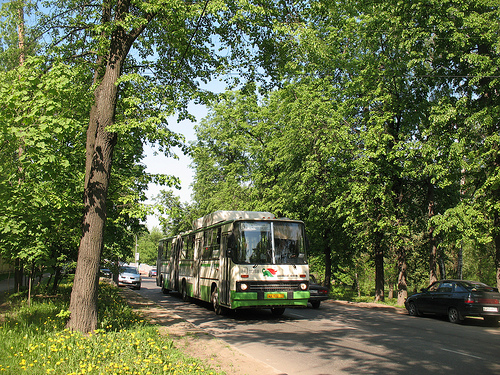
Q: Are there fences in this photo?
A: No, there are no fences.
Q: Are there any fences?
A: No, there are no fences.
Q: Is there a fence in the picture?
A: No, there are no fences.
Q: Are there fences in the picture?
A: No, there are no fences.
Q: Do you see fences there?
A: No, there are no fences.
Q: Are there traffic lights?
A: No, there are no traffic lights.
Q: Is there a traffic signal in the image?
A: No, there are no traffic lights.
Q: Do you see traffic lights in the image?
A: No, there are no traffic lights.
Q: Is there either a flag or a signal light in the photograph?
A: No, there are no traffic lights or flags.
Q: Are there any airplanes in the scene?
A: No, there are no airplanes.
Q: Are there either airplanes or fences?
A: No, there are no airplanes or fences.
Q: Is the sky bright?
A: Yes, the sky is bright.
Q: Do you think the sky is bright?
A: Yes, the sky is bright.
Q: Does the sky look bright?
A: Yes, the sky is bright.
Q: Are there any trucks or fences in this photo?
A: No, there are no fences or trucks.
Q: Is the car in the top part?
A: No, the car is in the bottom of the image.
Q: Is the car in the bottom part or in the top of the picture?
A: The car is in the bottom of the image.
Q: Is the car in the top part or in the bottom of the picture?
A: The car is in the bottom of the image.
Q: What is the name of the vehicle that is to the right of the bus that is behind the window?
A: The vehicle is a car.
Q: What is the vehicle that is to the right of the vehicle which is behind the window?
A: The vehicle is a car.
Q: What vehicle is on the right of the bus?
A: The vehicle is a car.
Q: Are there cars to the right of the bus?
A: Yes, there is a car to the right of the bus.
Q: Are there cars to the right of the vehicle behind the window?
A: Yes, there is a car to the right of the bus.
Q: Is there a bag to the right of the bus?
A: No, there is a car to the right of the bus.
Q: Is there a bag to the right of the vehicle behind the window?
A: No, there is a car to the right of the bus.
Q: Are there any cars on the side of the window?
A: Yes, there is a car on the side of the window.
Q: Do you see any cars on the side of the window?
A: Yes, there is a car on the side of the window.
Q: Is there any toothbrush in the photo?
A: No, there are no toothbrushes.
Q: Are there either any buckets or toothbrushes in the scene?
A: No, there are no toothbrushes or buckets.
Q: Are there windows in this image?
A: Yes, there is a window.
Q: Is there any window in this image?
A: Yes, there is a window.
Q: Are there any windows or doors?
A: Yes, there is a window.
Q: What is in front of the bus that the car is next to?
A: The window is in front of the bus.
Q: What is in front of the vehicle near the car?
A: The window is in front of the bus.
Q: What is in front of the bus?
A: The window is in front of the bus.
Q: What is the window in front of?
A: The window is in front of the bus.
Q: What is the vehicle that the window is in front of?
A: The vehicle is a bus.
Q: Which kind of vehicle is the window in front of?
A: The window is in front of the bus.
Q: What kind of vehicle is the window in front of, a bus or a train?
A: The window is in front of a bus.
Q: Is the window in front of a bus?
A: Yes, the window is in front of a bus.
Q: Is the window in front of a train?
A: No, the window is in front of a bus.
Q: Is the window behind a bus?
A: No, the window is in front of a bus.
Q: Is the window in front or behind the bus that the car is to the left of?
A: The window is in front of the bus.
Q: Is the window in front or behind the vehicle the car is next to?
A: The window is in front of the bus.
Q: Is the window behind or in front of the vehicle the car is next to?
A: The window is in front of the bus.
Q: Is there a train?
A: No, there are no trains.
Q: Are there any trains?
A: No, there are no trains.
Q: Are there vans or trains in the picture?
A: No, there are no trains or vans.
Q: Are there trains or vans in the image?
A: No, there are no trains or vans.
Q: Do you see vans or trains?
A: No, there are no trains or vans.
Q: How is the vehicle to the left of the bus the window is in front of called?
A: The vehicle is a car.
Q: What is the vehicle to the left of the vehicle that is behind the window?
A: The vehicle is a car.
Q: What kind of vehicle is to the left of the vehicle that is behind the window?
A: The vehicle is a car.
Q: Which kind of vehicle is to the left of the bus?
A: The vehicle is a car.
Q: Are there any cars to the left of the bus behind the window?
A: Yes, there is a car to the left of the bus.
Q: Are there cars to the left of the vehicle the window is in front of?
A: Yes, there is a car to the left of the bus.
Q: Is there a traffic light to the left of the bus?
A: No, there is a car to the left of the bus.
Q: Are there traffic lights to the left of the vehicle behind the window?
A: No, there is a car to the left of the bus.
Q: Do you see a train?
A: No, there are no trains.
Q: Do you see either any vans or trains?
A: No, there are no trains or vans.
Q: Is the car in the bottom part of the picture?
A: Yes, the car is in the bottom of the image.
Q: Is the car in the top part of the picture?
A: No, the car is in the bottom of the image.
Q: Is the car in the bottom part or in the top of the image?
A: The car is in the bottom of the image.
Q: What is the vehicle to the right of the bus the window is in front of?
A: The vehicle is a car.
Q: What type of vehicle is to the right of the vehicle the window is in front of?
A: The vehicle is a car.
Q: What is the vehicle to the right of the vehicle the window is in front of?
A: The vehicle is a car.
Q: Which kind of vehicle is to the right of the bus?
A: The vehicle is a car.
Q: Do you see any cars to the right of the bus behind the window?
A: Yes, there is a car to the right of the bus.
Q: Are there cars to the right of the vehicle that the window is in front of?
A: Yes, there is a car to the right of the bus.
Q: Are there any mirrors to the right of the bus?
A: No, there is a car to the right of the bus.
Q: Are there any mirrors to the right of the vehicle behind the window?
A: No, there is a car to the right of the bus.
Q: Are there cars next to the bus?
A: Yes, there is a car next to the bus.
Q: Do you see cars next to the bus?
A: Yes, there is a car next to the bus.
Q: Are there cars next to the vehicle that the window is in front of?
A: Yes, there is a car next to the bus.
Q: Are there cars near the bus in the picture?
A: Yes, there is a car near the bus.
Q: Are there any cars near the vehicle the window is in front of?
A: Yes, there is a car near the bus.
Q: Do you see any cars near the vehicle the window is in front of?
A: Yes, there is a car near the bus.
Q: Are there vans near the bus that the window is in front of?
A: No, there is a car near the bus.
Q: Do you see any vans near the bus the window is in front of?
A: No, there is a car near the bus.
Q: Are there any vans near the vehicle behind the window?
A: No, there is a car near the bus.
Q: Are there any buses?
A: Yes, there is a bus.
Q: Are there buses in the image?
A: Yes, there is a bus.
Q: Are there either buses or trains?
A: Yes, there is a bus.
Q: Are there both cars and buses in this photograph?
A: Yes, there are both a bus and a car.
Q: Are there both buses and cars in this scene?
A: Yes, there are both a bus and a car.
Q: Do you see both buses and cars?
A: Yes, there are both a bus and a car.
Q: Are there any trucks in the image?
A: No, there are no trucks.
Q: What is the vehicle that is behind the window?
A: The vehicle is a bus.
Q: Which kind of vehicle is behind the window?
A: The vehicle is a bus.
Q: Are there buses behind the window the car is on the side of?
A: Yes, there is a bus behind the window.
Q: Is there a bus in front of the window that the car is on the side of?
A: No, the bus is behind the window.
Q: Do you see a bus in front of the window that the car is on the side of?
A: No, the bus is behind the window.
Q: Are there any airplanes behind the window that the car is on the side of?
A: No, there is a bus behind the window.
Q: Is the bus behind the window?
A: Yes, the bus is behind the window.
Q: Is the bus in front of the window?
A: No, the bus is behind the window.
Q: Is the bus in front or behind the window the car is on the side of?
A: The bus is behind the window.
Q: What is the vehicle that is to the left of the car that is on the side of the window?
A: The vehicle is a bus.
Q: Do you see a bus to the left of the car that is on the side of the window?
A: Yes, there is a bus to the left of the car.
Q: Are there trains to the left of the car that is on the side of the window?
A: No, there is a bus to the left of the car.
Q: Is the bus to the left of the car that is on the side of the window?
A: Yes, the bus is to the left of the car.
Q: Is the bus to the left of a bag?
A: No, the bus is to the left of the car.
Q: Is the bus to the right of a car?
A: No, the bus is to the left of a car.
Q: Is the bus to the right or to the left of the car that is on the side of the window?
A: The bus is to the left of the car.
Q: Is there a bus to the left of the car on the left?
A: No, the bus is to the right of the car.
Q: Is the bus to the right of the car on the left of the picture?
A: Yes, the bus is to the right of the car.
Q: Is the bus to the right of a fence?
A: No, the bus is to the right of the car.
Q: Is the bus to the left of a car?
A: No, the bus is to the right of a car.